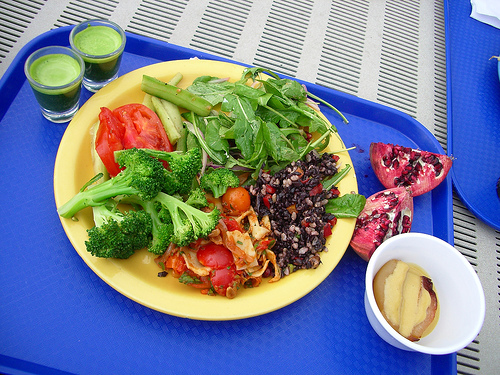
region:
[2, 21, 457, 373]
A blue plastic tray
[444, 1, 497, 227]
A food tray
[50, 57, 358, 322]
A yellow dinner plate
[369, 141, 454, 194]
A piece of fruit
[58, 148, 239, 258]
A serving of brocoli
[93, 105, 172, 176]
A sliced tomato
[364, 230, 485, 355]
A filled white bowl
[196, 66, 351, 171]
Fresh green spinach leaves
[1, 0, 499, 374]
A white table with notches in it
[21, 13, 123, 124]
two containers of salad dressing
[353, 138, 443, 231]
sliced pomegranates on a blue tray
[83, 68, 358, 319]
yellow plate with vegetables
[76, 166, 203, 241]
broccoli on the yellow plate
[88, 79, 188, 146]
sliced tomatoes and celery on a yellow plate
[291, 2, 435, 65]
outdoor table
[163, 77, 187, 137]
celery sticks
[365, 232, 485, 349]
small white bowl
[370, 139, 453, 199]
wedge of a pomegranate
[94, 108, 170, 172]
slices of red tomato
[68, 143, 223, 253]
green broccoli on yellow plate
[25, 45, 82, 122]
green beverage in a clear glass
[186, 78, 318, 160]
pile of green salad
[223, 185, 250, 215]
reddish orange cherry tomato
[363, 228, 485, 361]
small white bowl with food inside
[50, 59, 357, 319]
vegetables on a yellow plate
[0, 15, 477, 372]
blue tray with food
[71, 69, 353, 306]
Salad on a yellow tray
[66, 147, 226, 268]
broccoli on the plate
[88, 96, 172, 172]
tomato on the plate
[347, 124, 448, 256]
fruit on the tray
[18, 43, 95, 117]
green juice in a shot glass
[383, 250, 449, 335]
desert in a small bowl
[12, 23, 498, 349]
lunch on a blue tray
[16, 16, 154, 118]
two shot glasses on the tray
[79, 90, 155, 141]
tomatoes on the plate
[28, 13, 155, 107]
two glasses in plate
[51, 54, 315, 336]
a plate in the plate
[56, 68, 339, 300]
a round plate in plate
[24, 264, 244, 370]
a clear view of plate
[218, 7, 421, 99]
a part of iron stand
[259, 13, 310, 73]
holes in the iron stand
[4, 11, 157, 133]
two glasses with juice